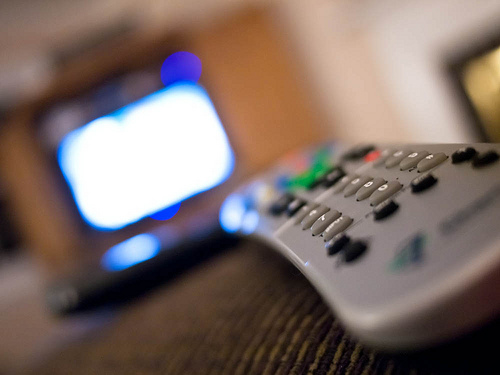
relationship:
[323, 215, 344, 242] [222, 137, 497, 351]
button on remote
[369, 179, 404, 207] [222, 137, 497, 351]
button on remote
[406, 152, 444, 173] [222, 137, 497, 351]
button on remote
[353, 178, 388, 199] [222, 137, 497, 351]
button on remote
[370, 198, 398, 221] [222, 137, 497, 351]
button on remote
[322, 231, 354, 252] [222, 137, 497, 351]
button on remote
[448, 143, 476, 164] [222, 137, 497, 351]
button on remote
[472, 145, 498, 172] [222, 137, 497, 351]
button on remote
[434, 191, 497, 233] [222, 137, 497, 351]
logo on remote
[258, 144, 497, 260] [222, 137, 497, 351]
buttons on remote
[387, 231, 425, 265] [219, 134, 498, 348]
logo of controller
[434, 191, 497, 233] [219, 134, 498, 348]
logo of controller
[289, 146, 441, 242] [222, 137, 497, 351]
numbers on remote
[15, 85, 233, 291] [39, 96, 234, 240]
entertainment system housing tv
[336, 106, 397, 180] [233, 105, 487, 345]
record button on controller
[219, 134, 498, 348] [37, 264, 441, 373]
controller on couch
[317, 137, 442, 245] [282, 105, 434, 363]
buttons on remote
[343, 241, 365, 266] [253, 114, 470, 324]
button on remote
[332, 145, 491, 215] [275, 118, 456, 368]
buttons on remote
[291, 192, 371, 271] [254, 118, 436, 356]
button on remote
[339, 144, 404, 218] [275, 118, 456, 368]
button on remote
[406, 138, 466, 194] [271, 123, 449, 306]
button on remote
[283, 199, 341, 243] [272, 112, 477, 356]
button on remote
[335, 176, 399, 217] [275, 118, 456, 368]
button on remote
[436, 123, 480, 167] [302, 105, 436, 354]
button on remote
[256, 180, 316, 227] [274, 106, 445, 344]
button on remote